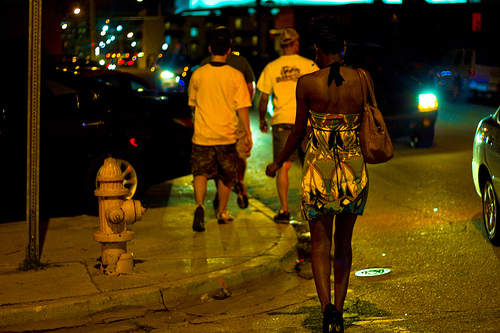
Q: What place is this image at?
A: It is at the street.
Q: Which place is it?
A: It is a street.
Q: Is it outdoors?
A: Yes, it is outdoors.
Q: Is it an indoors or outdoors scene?
A: It is outdoors.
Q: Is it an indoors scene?
A: No, it is outdoors.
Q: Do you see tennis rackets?
A: No, there are no tennis rackets.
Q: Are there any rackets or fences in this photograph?
A: No, there are no rackets or fences.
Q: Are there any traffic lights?
A: No, there are no traffic lights.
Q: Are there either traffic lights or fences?
A: No, there are no traffic lights or fences.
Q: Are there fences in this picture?
A: No, there are no fences.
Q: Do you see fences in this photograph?
A: No, there are no fences.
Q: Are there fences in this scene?
A: No, there are no fences.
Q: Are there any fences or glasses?
A: No, there are no fences or glasses.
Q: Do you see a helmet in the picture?
A: No, there are no helmets.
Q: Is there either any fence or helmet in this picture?
A: No, there are no helmets or fences.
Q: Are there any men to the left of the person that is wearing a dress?
A: Yes, there is a man to the left of the person.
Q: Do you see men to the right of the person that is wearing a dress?
A: No, the man is to the left of the person.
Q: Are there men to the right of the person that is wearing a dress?
A: No, the man is to the left of the person.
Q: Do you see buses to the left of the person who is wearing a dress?
A: No, there is a man to the left of the person.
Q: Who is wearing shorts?
A: The man is wearing shorts.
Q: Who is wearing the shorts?
A: The man is wearing shorts.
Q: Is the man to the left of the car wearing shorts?
A: Yes, the man is wearing shorts.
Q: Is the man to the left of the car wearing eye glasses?
A: No, the man is wearing shorts.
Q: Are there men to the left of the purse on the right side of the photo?
A: Yes, there is a man to the left of the purse.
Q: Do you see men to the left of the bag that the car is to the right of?
A: Yes, there is a man to the left of the purse.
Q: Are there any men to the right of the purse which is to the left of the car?
A: No, the man is to the left of the purse.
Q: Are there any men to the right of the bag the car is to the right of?
A: No, the man is to the left of the purse.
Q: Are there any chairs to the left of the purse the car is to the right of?
A: No, there is a man to the left of the purse.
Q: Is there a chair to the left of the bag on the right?
A: No, there is a man to the left of the purse.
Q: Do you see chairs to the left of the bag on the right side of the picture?
A: No, there is a man to the left of the purse.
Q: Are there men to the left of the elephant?
A: Yes, there is a man to the left of the elephant.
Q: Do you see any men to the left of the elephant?
A: Yes, there is a man to the left of the elephant.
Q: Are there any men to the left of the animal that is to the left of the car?
A: Yes, there is a man to the left of the elephant.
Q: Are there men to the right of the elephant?
A: No, the man is to the left of the elephant.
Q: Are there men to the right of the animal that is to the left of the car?
A: No, the man is to the left of the elephant.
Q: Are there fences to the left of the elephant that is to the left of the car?
A: No, there is a man to the left of the elephant.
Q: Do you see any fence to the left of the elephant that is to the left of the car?
A: No, there is a man to the left of the elephant.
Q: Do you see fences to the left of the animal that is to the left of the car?
A: No, there is a man to the left of the elephant.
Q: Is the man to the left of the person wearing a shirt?
A: Yes, the man is wearing a shirt.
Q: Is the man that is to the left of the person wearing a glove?
A: No, the man is wearing a shirt.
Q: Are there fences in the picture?
A: No, there are no fences.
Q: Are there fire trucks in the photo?
A: No, there are no fire trucks.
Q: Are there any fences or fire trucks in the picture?
A: No, there are no fire trucks or fences.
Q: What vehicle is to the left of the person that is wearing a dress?
A: The vehicle is a car.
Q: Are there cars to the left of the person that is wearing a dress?
A: Yes, there is a car to the left of the person.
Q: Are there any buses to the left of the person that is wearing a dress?
A: No, there is a car to the left of the person.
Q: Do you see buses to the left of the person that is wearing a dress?
A: No, there is a car to the left of the person.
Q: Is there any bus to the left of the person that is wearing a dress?
A: No, there is a car to the left of the person.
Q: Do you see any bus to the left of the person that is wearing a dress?
A: No, there is a car to the left of the person.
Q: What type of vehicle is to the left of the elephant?
A: The vehicle is a car.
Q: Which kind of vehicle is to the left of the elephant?
A: The vehicle is a car.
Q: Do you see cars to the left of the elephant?
A: Yes, there is a car to the left of the elephant.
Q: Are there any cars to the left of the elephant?
A: Yes, there is a car to the left of the elephant.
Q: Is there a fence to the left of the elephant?
A: No, there is a car to the left of the elephant.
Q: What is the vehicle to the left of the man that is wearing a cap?
A: The vehicle is a car.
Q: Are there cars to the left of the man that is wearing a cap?
A: Yes, there is a car to the left of the man.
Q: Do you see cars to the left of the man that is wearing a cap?
A: Yes, there is a car to the left of the man.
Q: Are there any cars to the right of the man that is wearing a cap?
A: No, the car is to the left of the man.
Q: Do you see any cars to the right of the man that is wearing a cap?
A: No, the car is to the left of the man.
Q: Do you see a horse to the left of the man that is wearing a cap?
A: No, there is a car to the left of the man.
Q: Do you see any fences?
A: No, there are no fences.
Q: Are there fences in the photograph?
A: No, there are no fences.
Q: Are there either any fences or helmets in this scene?
A: No, there are no fences or helmets.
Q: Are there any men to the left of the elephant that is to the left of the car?
A: Yes, there is a man to the left of the elephant.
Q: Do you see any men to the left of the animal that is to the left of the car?
A: Yes, there is a man to the left of the elephant.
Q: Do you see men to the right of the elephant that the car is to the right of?
A: No, the man is to the left of the elephant.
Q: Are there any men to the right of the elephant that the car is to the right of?
A: No, the man is to the left of the elephant.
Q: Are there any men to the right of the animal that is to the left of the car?
A: No, the man is to the left of the elephant.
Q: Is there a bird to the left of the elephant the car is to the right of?
A: No, there is a man to the left of the elephant.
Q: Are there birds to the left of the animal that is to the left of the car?
A: No, there is a man to the left of the elephant.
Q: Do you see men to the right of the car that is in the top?
A: Yes, there is a man to the right of the car.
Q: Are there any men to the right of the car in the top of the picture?
A: Yes, there is a man to the right of the car.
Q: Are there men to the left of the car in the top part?
A: No, the man is to the right of the car.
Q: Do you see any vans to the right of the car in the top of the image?
A: No, there is a man to the right of the car.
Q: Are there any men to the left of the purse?
A: Yes, there is a man to the left of the purse.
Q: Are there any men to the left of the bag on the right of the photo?
A: Yes, there is a man to the left of the purse.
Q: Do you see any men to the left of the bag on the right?
A: Yes, there is a man to the left of the purse.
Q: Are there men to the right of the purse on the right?
A: No, the man is to the left of the purse.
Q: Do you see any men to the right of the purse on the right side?
A: No, the man is to the left of the purse.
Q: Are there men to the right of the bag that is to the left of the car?
A: No, the man is to the left of the purse.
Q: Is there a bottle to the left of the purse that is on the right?
A: No, there is a man to the left of the purse.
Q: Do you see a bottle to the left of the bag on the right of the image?
A: No, there is a man to the left of the purse.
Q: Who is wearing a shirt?
A: The man is wearing a shirt.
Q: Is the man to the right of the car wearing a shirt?
A: Yes, the man is wearing a shirt.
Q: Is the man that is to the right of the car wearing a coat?
A: No, the man is wearing a shirt.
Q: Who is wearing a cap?
A: The man is wearing a cap.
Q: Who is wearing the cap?
A: The man is wearing a cap.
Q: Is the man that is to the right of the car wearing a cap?
A: Yes, the man is wearing a cap.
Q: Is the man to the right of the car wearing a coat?
A: No, the man is wearing a cap.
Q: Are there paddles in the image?
A: No, there are no paddles.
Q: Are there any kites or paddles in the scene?
A: No, there are no paddles or kites.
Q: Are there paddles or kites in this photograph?
A: No, there are no paddles or kites.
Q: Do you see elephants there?
A: Yes, there is an elephant.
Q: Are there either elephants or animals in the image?
A: Yes, there is an elephant.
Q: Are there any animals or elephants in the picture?
A: Yes, there is an elephant.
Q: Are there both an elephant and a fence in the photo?
A: No, there is an elephant but no fences.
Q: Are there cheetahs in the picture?
A: No, there are no cheetahs.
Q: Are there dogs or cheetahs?
A: No, there are no cheetahs or dogs.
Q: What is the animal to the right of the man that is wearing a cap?
A: The animal is an elephant.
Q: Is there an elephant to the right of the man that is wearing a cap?
A: Yes, there is an elephant to the right of the man.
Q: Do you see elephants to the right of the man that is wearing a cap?
A: Yes, there is an elephant to the right of the man.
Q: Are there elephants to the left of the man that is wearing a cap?
A: No, the elephant is to the right of the man.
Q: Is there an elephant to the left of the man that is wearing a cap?
A: No, the elephant is to the right of the man.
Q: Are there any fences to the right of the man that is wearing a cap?
A: No, there is an elephant to the right of the man.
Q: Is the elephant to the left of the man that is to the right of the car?
A: No, the elephant is to the right of the man.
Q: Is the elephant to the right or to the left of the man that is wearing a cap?
A: The elephant is to the right of the man.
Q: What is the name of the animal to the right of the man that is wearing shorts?
A: The animal is an elephant.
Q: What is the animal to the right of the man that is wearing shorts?
A: The animal is an elephant.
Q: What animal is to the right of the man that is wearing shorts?
A: The animal is an elephant.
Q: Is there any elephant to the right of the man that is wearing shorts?
A: Yes, there is an elephant to the right of the man.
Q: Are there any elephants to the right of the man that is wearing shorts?
A: Yes, there is an elephant to the right of the man.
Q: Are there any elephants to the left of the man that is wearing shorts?
A: No, the elephant is to the right of the man.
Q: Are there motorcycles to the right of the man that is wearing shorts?
A: No, there is an elephant to the right of the man.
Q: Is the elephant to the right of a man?
A: Yes, the elephant is to the right of a man.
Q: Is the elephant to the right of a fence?
A: No, the elephant is to the right of a man.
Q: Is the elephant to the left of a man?
A: No, the elephant is to the right of a man.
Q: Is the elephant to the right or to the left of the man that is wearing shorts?
A: The elephant is to the right of the man.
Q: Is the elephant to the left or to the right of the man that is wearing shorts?
A: The elephant is to the right of the man.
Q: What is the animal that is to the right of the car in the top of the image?
A: The animal is an elephant.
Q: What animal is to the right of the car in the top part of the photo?
A: The animal is an elephant.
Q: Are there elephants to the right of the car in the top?
A: Yes, there is an elephant to the right of the car.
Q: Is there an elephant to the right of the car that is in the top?
A: Yes, there is an elephant to the right of the car.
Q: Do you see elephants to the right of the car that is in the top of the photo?
A: Yes, there is an elephant to the right of the car.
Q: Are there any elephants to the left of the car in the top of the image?
A: No, the elephant is to the right of the car.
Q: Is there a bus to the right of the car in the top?
A: No, there is an elephant to the right of the car.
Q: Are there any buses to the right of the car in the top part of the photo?
A: No, there is an elephant to the right of the car.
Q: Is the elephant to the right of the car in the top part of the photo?
A: Yes, the elephant is to the right of the car.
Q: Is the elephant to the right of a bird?
A: No, the elephant is to the right of the car.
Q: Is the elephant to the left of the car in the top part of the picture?
A: No, the elephant is to the right of the car.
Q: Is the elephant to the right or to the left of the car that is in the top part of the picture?
A: The elephant is to the right of the car.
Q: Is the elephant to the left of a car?
A: Yes, the elephant is to the left of a car.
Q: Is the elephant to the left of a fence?
A: No, the elephant is to the left of a car.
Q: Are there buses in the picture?
A: No, there are no buses.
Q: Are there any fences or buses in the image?
A: No, there are no buses or fences.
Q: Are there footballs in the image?
A: No, there are no footballs.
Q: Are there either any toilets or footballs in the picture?
A: No, there are no footballs or toilets.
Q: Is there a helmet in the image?
A: No, there are no helmets.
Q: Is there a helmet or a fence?
A: No, there are no helmets or fences.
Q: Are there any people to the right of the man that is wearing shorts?
A: Yes, there is a person to the right of the man.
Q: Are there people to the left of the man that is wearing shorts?
A: No, the person is to the right of the man.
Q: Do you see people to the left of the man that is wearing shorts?
A: No, the person is to the right of the man.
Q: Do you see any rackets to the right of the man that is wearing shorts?
A: No, there is a person to the right of the man.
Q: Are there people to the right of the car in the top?
A: Yes, there is a person to the right of the car.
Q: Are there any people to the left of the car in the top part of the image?
A: No, the person is to the right of the car.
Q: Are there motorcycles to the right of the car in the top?
A: No, there is a person to the right of the car.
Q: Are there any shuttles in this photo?
A: No, there are no shuttles.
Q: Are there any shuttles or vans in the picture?
A: No, there are no shuttles or vans.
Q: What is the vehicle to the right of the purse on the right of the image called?
A: The vehicle is a car.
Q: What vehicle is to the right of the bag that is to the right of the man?
A: The vehicle is a car.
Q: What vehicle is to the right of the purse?
A: The vehicle is a car.